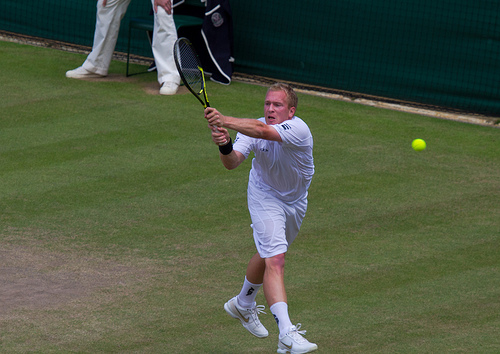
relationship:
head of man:
[257, 80, 302, 133] [205, 76, 329, 353]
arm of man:
[205, 106, 312, 155] [205, 76, 329, 353]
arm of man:
[206, 115, 267, 172] [205, 76, 329, 353]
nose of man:
[267, 101, 277, 118] [205, 76, 329, 353]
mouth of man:
[266, 114, 277, 124] [205, 76, 329, 353]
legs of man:
[248, 202, 294, 333] [205, 76, 329, 353]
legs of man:
[237, 202, 302, 319] [205, 76, 329, 353]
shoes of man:
[271, 323, 319, 352] [205, 76, 329, 353]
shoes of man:
[219, 292, 274, 341] [205, 76, 329, 353]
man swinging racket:
[205, 76, 329, 353] [170, 34, 227, 148]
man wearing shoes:
[205, 76, 329, 353] [271, 323, 319, 352]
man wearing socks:
[205, 76, 329, 353] [266, 297, 297, 336]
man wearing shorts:
[205, 76, 329, 353] [241, 177, 310, 261]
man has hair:
[205, 76, 329, 353] [267, 78, 299, 114]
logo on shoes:
[280, 339, 295, 352] [271, 323, 319, 352]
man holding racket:
[205, 76, 329, 353] [170, 34, 227, 148]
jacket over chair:
[146, 2, 236, 83] [122, 1, 216, 91]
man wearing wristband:
[205, 76, 329, 353] [215, 136, 236, 158]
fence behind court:
[3, 1, 500, 132] [2, 35, 499, 353]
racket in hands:
[170, 34, 227, 148] [206, 106, 232, 149]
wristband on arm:
[215, 136, 236, 158] [206, 115, 267, 172]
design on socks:
[271, 314, 281, 327] [266, 297, 297, 336]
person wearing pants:
[61, 0, 185, 98] [85, 1, 184, 89]